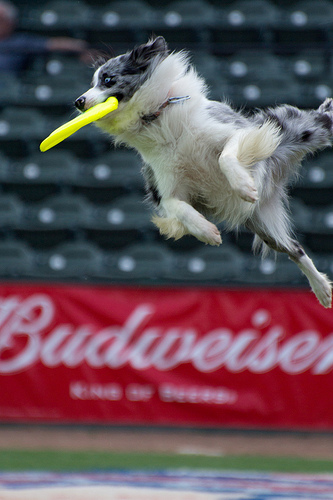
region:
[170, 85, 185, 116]
part of a chian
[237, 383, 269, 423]
part of a banner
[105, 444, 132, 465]
part of a grass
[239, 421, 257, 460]
edge fo a banner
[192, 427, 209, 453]
part of a ground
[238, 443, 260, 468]
part of a ground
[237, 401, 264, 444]
part of a banner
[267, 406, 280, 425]
part of a banner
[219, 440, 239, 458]
part of a ground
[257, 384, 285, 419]
part of a banner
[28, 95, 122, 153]
Yellow frisbee being caught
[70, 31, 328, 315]
Jumping dog catching frisbee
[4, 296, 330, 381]
Budweiser advertisement sign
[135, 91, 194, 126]
Collar on dog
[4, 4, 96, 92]
Solitary person watching exhibition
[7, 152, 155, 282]
Empty arena seats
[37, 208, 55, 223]
Blurry seat number identifier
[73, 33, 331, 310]
Dog jumping in the air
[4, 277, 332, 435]
Red Budweiser beer advertisement banner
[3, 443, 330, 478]
Out of focus green patch on field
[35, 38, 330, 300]
an airborne dog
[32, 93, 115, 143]
a yellow frisbee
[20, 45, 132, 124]
a dog holding a frisbee in its mouth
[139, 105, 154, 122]
a brown leather collar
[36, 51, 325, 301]
a dog playing with a frisbee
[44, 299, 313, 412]
a red signboard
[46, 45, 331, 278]
a black and white dog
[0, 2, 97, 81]
an old man with white hair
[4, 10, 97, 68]
a man with a stretched arm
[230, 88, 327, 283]
a dog with its legs astride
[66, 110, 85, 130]
edge of a dish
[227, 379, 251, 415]
part of a banner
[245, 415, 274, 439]
edge of a banner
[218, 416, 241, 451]
part of an edge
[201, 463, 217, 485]
part of a field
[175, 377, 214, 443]
part of a banner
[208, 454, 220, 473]
part of a grass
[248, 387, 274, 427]
part of a banner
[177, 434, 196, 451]
part of a ground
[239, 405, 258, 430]
edge of a banner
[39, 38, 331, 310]
Dog mid air catching a frisbee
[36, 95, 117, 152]
Yellow frisbee that the dog is catching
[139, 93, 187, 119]
Collar on the dog catching the frisbee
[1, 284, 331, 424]
Beer advertising sign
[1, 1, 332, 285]
Seats in stands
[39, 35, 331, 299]
Dog catching a frisbee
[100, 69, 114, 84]
Blue eye of the dog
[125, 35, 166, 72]
Ear of the dog catching frisbee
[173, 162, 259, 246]
Front paws of the dog catching a frisbee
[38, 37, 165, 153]
Face of the dog catching a frisbee